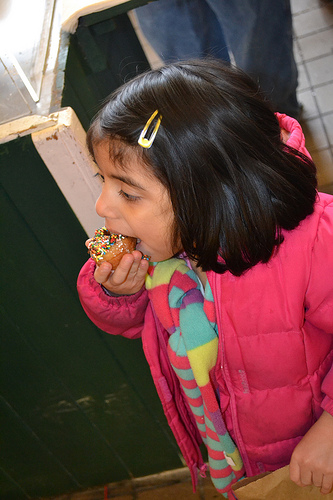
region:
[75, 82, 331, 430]
young girl eating donut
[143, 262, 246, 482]
young girl wearing colorful striped scarf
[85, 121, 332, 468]
young girl wearing bright pink coat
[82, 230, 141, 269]
donut with muticolored sprinkles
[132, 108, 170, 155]
gold barette in girl's hair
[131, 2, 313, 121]
person wearing blue jeans standing behind girl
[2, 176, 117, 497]
girl standing next to green wall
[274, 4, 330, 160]
floor with white tile and black grout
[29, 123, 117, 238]
white trim on the wall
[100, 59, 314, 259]
young girl with dark brown hair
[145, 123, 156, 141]
hair clip of a girl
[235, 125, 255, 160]
section of a girls hair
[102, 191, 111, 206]
section of a girls nose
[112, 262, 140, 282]
fingers of a small girl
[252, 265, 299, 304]
section of a girls jacket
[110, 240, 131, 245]
section of a cup cake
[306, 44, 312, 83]
section of a white surface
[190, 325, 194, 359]
section of a girls scarf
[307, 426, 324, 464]
left hand of a small girl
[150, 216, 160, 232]
cheeks of a small girl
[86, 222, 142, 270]
cake donut with colored sprinkles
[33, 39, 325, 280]
young girl eating a donut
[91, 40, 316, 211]
girl with dark and shiny hair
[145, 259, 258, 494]
girl wearing a striped scarf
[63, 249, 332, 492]
puffy pink cold-weather coat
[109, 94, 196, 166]
yellow barrette in hair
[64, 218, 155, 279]
donut is first meal of day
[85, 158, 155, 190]
thick and full eyebrows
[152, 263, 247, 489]
scarf colors compliment coat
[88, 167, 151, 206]
girl has brown eyes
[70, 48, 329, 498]
little girl eating a pastry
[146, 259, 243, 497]
colorful winter scarf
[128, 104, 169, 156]
hair barrette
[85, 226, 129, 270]
pastry with sprinkles on it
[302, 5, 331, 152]
tiled floor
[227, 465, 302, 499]
brown paper bag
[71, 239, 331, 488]
pink winter coat worn by little girl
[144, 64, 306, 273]
girl's black hair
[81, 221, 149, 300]
hand holding a pastry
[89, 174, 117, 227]
profile of a nose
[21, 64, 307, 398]
A girl is eating a treat.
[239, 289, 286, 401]
The girl is wearing a pink coat.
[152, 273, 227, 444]
The girl is wearing a scarf.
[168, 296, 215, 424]
The scarf has multiple colors.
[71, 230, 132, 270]
The treat has candy on top.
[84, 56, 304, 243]
The girl's hair is shoulder length.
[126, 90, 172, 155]
The girl has a yellow clasp in her hair.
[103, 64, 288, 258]
The girl's hair is dark brown.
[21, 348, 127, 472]
The wall is painted green.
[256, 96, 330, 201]
The girl has a hood on her coat.